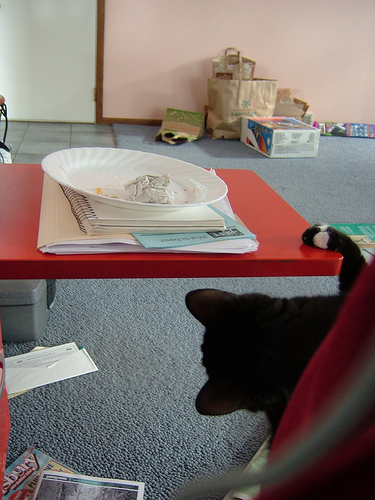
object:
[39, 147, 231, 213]
plate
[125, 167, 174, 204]
napkin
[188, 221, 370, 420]
cat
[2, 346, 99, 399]
envelope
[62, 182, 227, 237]
notebook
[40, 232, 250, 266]
papers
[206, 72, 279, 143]
bags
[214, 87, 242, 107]
brown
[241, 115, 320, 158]
box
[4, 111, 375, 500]
floor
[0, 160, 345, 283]
table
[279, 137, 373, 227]
carpet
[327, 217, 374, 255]
newspaper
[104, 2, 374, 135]
wall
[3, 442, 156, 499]
magazine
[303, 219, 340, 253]
paw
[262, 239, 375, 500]
blanket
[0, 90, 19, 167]
stool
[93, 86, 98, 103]
hinges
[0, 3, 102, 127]
door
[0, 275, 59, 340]
tackle box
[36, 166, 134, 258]
folder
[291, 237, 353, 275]
corner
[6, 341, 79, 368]
contents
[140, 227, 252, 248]
paper